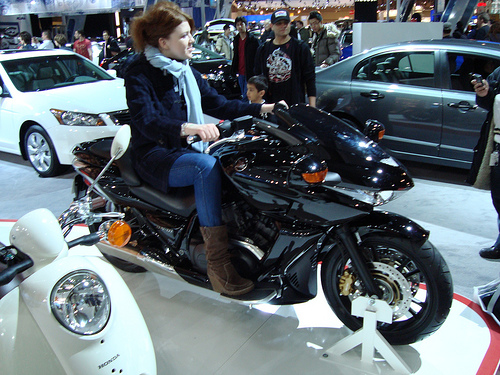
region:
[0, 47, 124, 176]
White car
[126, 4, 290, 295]
Girl sitting on motorcycle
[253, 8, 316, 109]
Man standing in black and white hat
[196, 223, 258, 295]
Brown boot a girl is wearing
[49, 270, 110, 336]
Headlight of a white scooter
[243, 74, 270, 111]
A dark haired small boy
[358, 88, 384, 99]
Door handle of a car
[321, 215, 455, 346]
Front wheel of motorcycle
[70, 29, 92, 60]
Man in red shirt looking away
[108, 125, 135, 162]
white rear view mirror on white scooter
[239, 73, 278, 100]
Little boy's head standing in front of man with black shirt.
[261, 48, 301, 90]
Design on black shirt man with hat is wearing.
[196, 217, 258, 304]
Brown boot woman on motorcycle is wearing.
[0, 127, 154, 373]
White Honda cycle.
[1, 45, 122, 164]
White car behind woman on motorcycle.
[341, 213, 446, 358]
Front wheel on motorcycle.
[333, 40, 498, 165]
Grayish-black car behind man with black shirt with design on it.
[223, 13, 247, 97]
Man in burgundy shirt with open black jacket over it.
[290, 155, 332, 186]
Left blinker light on black motorcycle woman is sitting on.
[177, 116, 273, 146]
Left handle on motorcycle woman is sitting on.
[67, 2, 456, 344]
Person on a black motorcycle.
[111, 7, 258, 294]
Person wearing brown boots.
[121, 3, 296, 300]
Person wearing a scarf.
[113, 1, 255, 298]
Person wearing jeans.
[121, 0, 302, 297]
Person with brown hair.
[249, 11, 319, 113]
Person wearing a hat.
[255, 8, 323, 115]
Person wearing a black shirt.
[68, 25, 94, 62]
Person wearing a red shirt.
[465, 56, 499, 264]
Person holding a phone.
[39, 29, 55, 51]
Person wearing a white shirt.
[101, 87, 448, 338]
A black motorcycle.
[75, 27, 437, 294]
A woman riding a black motorcycle.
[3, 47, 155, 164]
A white car.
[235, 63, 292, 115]
A young boy looking on.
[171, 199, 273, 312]
A woman's brown boots.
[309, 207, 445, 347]
A black motorcycle wheel.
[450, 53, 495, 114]
A cellphone in hand.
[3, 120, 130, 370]
A white mopede.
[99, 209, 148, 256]
A orange blinker.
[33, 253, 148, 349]
A headlight attached to a bike.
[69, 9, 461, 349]
A girl on motorbike.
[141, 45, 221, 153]
A scarf around lady's neck.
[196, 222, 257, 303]
A lady wearing brown boots.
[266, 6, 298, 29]
Man wearing a black cap.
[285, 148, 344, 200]
Orange signal light on motorbike.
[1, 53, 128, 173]
A white car behind motorbike.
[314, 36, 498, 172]
A blue car next to motorbike.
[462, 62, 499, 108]
A person taking pictures.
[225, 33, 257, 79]
Man wearing red shirt and black jacket.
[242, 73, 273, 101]
Head of a little boy.